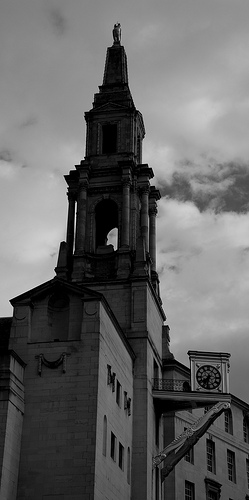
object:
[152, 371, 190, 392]
fence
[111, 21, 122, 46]
statue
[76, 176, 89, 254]
columns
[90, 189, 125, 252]
arches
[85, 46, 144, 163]
parapets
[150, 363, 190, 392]
balcony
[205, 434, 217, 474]
windows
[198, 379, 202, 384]
roman numerals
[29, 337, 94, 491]
wall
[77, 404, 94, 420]
brick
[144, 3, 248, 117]
sky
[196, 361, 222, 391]
face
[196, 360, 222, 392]
clock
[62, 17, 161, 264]
tower